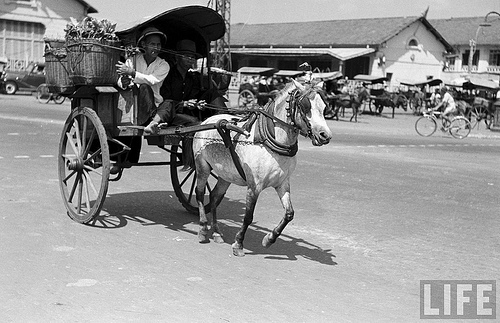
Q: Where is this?
A: This is at the road.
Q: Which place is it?
A: It is a road.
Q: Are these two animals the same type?
A: Yes, all the animals are horses.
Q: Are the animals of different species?
A: No, all the animals are horses.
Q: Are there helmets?
A: No, there are no helmets.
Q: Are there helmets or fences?
A: No, there are no helmets or fences.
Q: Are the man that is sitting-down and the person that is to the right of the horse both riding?
A: Yes, both the man and the person are riding.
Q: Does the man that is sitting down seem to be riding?
A: Yes, the man is riding.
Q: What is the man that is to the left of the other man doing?
A: The man is riding.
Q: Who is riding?
A: The man is riding.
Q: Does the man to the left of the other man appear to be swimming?
A: No, the man is riding.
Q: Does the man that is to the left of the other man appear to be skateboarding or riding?
A: The man is riding.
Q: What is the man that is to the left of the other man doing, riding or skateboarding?
A: The man is riding.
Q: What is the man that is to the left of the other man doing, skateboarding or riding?
A: The man is riding.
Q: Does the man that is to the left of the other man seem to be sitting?
A: Yes, the man is sitting.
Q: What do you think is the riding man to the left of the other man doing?
A: The man is sitting.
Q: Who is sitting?
A: The man is sitting.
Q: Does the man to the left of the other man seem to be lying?
A: No, the man is sitting.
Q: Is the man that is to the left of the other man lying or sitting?
A: The man is sitting.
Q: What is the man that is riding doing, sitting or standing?
A: The man is sitting.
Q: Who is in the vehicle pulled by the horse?
A: The man is in the carriage.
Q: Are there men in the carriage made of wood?
A: Yes, there is a man in the carriage.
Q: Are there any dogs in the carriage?
A: No, there is a man in the carriage.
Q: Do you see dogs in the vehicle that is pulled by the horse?
A: No, there is a man in the carriage.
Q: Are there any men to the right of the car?
A: Yes, there is a man to the right of the car.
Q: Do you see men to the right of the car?
A: Yes, there is a man to the right of the car.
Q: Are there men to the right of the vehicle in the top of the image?
A: Yes, there is a man to the right of the car.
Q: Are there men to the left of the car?
A: No, the man is to the right of the car.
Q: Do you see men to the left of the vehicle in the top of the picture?
A: No, the man is to the right of the car.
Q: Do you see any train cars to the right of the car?
A: No, there is a man to the right of the car.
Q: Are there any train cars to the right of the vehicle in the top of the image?
A: No, there is a man to the right of the car.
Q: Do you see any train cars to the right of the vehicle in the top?
A: No, there is a man to the right of the car.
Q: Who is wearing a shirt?
A: The man is wearing a shirt.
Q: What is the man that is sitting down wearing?
A: The man is wearing a shirt.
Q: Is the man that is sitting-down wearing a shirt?
A: Yes, the man is wearing a shirt.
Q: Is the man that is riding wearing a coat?
A: No, the man is wearing a shirt.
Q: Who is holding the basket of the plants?
A: The man is holding the basket.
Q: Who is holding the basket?
A: The man is holding the basket.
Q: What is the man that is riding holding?
A: The man is holding the basket.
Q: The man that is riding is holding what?
A: The man is holding the basket.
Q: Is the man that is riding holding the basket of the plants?
A: Yes, the man is holding the basket.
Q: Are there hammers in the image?
A: No, there are no hammers.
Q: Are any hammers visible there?
A: No, there are no hammers.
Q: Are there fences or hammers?
A: No, there are no hammers or fences.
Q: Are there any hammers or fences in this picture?
A: No, there are no hammers or fences.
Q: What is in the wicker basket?
A: The plants are in the basket.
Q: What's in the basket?
A: The plants are in the basket.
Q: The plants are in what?
A: The plants are in the basket.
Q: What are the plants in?
A: The plants are in the basket.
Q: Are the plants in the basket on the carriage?
A: Yes, the plants are in the basket.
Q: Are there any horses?
A: Yes, there is a horse.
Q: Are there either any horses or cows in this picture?
A: Yes, there is a horse.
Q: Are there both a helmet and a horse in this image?
A: No, there is a horse but no helmets.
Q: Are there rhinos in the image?
A: No, there are no rhinos.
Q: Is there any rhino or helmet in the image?
A: No, there are no rhinos or helmets.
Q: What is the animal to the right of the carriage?
A: The animal is a horse.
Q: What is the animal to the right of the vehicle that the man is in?
A: The animal is a horse.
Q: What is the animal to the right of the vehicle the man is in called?
A: The animal is a horse.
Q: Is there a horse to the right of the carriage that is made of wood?
A: Yes, there is a horse to the right of the carriage.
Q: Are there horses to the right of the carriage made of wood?
A: Yes, there is a horse to the right of the carriage.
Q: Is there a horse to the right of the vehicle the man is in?
A: Yes, there is a horse to the right of the carriage.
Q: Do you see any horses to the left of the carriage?
A: No, the horse is to the right of the carriage.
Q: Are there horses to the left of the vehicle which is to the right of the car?
A: No, the horse is to the right of the carriage.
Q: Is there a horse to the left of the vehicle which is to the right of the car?
A: No, the horse is to the right of the carriage.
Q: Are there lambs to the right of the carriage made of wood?
A: No, there is a horse to the right of the carriage.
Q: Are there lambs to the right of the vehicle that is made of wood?
A: No, there is a horse to the right of the carriage.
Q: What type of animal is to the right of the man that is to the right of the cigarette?
A: The animal is a horse.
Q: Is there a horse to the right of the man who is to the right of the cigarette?
A: Yes, there is a horse to the right of the man.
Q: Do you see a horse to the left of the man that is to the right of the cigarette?
A: No, the horse is to the right of the man.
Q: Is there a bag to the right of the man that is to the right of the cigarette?
A: No, there is a horse to the right of the man.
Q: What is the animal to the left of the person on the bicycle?
A: The animal is a horse.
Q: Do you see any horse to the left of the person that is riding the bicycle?
A: Yes, there is a horse to the left of the person.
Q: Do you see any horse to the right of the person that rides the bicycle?
A: No, the horse is to the left of the person.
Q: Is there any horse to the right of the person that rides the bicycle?
A: No, the horse is to the left of the person.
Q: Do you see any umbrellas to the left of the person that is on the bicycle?
A: No, there is a horse to the left of the person.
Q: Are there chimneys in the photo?
A: No, there are no chimneys.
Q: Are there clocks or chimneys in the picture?
A: No, there are no chimneys or clocks.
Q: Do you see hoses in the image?
A: No, there are no hoses.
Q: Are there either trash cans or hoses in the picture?
A: No, there are no hoses or trash cans.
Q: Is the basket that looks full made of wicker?
A: Yes, the basket is made of wicker.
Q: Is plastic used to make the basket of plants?
A: No, the basket is made of wicker.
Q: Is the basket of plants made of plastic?
A: No, the basket is made of wicker.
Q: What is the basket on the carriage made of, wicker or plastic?
A: The basket is made of wicker.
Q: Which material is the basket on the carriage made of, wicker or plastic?
A: The basket is made of wicker.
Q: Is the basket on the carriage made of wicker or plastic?
A: The basket is made of wicker.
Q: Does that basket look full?
A: Yes, the basket is full.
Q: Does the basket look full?
A: Yes, the basket is full.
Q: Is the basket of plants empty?
A: No, the basket is full.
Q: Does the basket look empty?
A: No, the basket is full.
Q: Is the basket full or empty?
A: The basket is full.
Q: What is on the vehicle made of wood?
A: The basket is on the carriage.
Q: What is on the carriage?
A: The basket is on the carriage.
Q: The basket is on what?
A: The basket is on the carriage.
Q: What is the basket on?
A: The basket is on the carriage.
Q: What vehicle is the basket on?
A: The basket is on the carriage.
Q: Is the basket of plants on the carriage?
A: Yes, the basket is on the carriage.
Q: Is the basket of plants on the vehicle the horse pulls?
A: Yes, the basket is on the carriage.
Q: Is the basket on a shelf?
A: No, the basket is on the carriage.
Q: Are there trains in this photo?
A: No, there are no trains.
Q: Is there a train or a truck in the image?
A: No, there are no trains or trucks.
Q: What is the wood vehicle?
A: The vehicle is a carriage.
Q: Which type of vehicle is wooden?
A: The vehicle is a carriage.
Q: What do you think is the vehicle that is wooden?
A: The vehicle is a carriage.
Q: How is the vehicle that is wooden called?
A: The vehicle is a carriage.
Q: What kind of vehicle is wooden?
A: The vehicle is a carriage.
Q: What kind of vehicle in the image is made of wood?
A: The vehicle is a carriage.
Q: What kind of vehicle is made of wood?
A: The vehicle is a carriage.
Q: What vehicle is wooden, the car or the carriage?
A: The carriage is wooden.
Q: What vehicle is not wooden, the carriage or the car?
A: The car is not wooden.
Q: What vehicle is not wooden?
A: The vehicle is a car.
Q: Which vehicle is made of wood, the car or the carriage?
A: The carriage is made of wood.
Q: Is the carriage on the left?
A: Yes, the carriage is on the left of the image.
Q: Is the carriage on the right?
A: No, the carriage is on the left of the image.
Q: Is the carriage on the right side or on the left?
A: The carriage is on the left of the image.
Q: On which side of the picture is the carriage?
A: The carriage is on the left of the image.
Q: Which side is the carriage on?
A: The carriage is on the left of the image.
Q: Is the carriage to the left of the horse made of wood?
A: Yes, the carriage is made of wood.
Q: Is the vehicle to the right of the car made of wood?
A: Yes, the carriage is made of wood.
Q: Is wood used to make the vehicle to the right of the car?
A: Yes, the carriage is made of wood.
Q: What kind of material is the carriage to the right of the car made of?
A: The carriage is made of wood.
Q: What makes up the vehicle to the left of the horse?
A: The carriage is made of wood.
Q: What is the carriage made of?
A: The carriage is made of wood.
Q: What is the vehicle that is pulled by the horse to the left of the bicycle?
A: The vehicle is a carriage.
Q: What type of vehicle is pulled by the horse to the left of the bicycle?
A: The vehicle is a carriage.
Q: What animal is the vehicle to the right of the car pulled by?
A: The carriage is pulled by the horse.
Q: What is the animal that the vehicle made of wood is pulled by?
A: The animal is a horse.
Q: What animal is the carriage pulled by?
A: The carriage is pulled by the horse.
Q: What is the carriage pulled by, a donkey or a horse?
A: The carriage is pulled by a horse.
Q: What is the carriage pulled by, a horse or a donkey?
A: The carriage is pulled by a horse.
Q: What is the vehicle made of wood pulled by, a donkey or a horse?
A: The carriage is pulled by a horse.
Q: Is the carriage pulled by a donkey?
A: No, the carriage is pulled by the horse.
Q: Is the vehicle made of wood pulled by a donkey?
A: No, the carriage is pulled by the horse.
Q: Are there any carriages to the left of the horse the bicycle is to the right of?
A: Yes, there is a carriage to the left of the horse.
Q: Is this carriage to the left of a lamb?
A: No, the carriage is to the left of a horse.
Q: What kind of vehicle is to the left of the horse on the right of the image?
A: The vehicle is a carriage.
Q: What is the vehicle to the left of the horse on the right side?
A: The vehicle is a carriage.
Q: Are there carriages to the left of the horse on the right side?
A: Yes, there is a carriage to the left of the horse.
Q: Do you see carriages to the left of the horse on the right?
A: Yes, there is a carriage to the left of the horse.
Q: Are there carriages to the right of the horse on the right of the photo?
A: No, the carriage is to the left of the horse.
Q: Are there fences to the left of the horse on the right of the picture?
A: No, there is a carriage to the left of the horse.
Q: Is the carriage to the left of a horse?
A: Yes, the carriage is to the left of a horse.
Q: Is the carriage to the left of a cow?
A: No, the carriage is to the left of a horse.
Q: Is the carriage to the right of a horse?
A: No, the carriage is to the left of a horse.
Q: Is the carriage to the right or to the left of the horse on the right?
A: The carriage is to the left of the horse.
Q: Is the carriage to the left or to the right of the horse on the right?
A: The carriage is to the left of the horse.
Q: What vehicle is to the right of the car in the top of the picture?
A: The vehicle is a carriage.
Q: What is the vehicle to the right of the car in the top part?
A: The vehicle is a carriage.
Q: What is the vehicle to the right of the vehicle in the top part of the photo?
A: The vehicle is a carriage.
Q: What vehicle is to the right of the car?
A: The vehicle is a carriage.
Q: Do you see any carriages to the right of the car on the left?
A: Yes, there is a carriage to the right of the car.